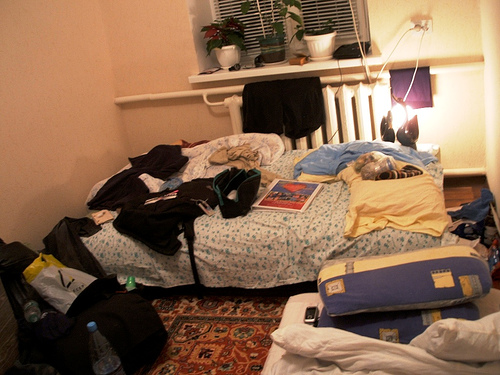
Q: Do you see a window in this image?
A: Yes, there is a window.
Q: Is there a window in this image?
A: Yes, there is a window.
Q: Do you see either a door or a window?
A: Yes, there is a window.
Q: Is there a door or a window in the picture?
A: Yes, there is a window.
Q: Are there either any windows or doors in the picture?
A: Yes, there is a window.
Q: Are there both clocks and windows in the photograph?
A: No, there is a window but no clocks.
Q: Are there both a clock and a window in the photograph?
A: No, there is a window but no clocks.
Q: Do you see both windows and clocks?
A: No, there is a window but no clocks.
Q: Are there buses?
A: No, there are no buses.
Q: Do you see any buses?
A: No, there are no buses.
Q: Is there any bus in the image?
A: No, there are no buses.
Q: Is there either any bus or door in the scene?
A: No, there are no buses or doors.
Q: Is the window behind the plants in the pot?
A: Yes, the window is behind the plants.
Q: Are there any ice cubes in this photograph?
A: No, there are no ice cubes.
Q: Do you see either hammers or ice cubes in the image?
A: No, there are no ice cubes or hammers.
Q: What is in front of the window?
A: The plants are in front of the window.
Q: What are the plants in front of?
A: The plants are in front of the window.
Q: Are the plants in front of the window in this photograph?
A: Yes, the plants are in front of the window.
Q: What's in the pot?
A: The plants are in the pot.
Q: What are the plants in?
A: The plants are in the pot.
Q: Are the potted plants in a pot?
A: Yes, the plants are in a pot.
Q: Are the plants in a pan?
A: No, the plants are in a pot.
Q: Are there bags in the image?
A: Yes, there is a bag.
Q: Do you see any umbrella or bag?
A: Yes, there is a bag.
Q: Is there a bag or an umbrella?
A: Yes, there is a bag.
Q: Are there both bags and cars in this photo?
A: No, there is a bag but no cars.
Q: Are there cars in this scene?
A: No, there are no cars.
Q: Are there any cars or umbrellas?
A: No, there are no cars or umbrellas.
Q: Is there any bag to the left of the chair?
A: Yes, there is a bag to the left of the chair.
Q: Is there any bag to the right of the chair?
A: No, the bag is to the left of the chair.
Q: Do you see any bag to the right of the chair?
A: No, the bag is to the left of the chair.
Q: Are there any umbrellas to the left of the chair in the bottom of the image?
A: No, there is a bag to the left of the chair.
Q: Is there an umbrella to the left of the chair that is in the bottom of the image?
A: No, there is a bag to the left of the chair.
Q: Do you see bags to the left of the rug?
A: Yes, there is a bag to the left of the rug.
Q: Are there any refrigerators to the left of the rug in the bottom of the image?
A: No, there is a bag to the left of the rug.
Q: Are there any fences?
A: No, there are no fences.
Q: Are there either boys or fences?
A: No, there are no fences or boys.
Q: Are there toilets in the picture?
A: No, there are no toilets.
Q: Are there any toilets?
A: No, there are no toilets.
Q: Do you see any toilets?
A: No, there are no toilets.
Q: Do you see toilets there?
A: No, there are no toilets.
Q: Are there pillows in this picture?
A: Yes, there is a pillow.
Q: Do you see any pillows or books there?
A: Yes, there is a pillow.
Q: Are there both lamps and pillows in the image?
A: Yes, there are both a pillow and a lamp.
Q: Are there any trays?
A: No, there are no trays.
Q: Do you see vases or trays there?
A: No, there are no trays or vases.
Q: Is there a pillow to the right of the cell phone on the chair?
A: Yes, there is a pillow to the right of the cellphone.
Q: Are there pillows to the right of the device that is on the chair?
A: Yes, there is a pillow to the right of the cellphone.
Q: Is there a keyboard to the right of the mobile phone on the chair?
A: No, there is a pillow to the right of the mobile phone.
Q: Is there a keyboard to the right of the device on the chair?
A: No, there is a pillow to the right of the mobile phone.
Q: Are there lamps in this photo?
A: Yes, there is a lamp.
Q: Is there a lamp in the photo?
A: Yes, there is a lamp.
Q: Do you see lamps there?
A: Yes, there is a lamp.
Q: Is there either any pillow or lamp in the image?
A: Yes, there is a lamp.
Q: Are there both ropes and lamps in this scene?
A: No, there is a lamp but no ropes.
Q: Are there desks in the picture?
A: No, there are no desks.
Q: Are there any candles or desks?
A: No, there are no desks or candles.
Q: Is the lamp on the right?
A: Yes, the lamp is on the right of the image.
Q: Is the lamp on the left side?
A: No, the lamp is on the right of the image.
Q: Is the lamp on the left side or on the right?
A: The lamp is on the right of the image.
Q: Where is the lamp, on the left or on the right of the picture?
A: The lamp is on the right of the image.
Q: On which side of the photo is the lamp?
A: The lamp is on the right of the image.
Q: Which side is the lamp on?
A: The lamp is on the right of the image.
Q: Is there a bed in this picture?
A: Yes, there is a bed.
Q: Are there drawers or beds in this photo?
A: Yes, there is a bed.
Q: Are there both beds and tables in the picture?
A: No, there is a bed but no tables.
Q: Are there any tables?
A: No, there are no tables.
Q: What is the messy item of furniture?
A: The piece of furniture is a bed.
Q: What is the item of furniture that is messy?
A: The piece of furniture is a bed.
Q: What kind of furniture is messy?
A: The furniture is a bed.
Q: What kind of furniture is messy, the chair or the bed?
A: The bed is messy.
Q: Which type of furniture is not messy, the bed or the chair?
A: The chair is not messy.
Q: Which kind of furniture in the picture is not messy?
A: The furniture is a chair.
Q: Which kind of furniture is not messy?
A: The furniture is a chair.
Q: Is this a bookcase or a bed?
A: This is a bed.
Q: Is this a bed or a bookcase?
A: This is a bed.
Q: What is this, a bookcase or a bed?
A: This is a bed.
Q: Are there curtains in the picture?
A: No, there are no curtains.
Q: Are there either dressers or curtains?
A: No, there are no curtains or dressers.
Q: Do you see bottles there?
A: Yes, there is a bottle.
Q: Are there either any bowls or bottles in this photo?
A: Yes, there is a bottle.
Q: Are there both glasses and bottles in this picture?
A: No, there is a bottle but no glasses.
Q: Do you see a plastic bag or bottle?
A: Yes, there is a plastic bottle.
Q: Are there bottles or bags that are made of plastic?
A: Yes, the bottle is made of plastic.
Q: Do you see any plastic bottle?
A: Yes, there is a bottle that is made of plastic.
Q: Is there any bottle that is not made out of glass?
A: Yes, there is a bottle that is made of plastic.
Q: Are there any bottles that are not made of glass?
A: Yes, there is a bottle that is made of plastic.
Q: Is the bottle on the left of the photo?
A: Yes, the bottle is on the left of the image.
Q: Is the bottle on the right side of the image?
A: No, the bottle is on the left of the image.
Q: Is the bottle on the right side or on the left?
A: The bottle is on the left of the image.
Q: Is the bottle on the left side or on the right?
A: The bottle is on the left of the image.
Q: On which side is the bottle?
A: The bottle is on the left of the image.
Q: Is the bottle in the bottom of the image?
A: Yes, the bottle is in the bottom of the image.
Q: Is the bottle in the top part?
A: No, the bottle is in the bottom of the image.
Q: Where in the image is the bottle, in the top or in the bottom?
A: The bottle is in the bottom of the image.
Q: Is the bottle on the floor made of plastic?
A: Yes, the bottle is made of plastic.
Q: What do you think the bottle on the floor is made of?
A: The bottle is made of plastic.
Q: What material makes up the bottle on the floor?
A: The bottle is made of plastic.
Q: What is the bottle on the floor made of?
A: The bottle is made of plastic.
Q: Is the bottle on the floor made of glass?
A: No, the bottle is made of plastic.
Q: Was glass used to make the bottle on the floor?
A: No, the bottle is made of plastic.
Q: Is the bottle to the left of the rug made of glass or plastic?
A: The bottle is made of plastic.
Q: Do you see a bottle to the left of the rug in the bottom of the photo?
A: Yes, there is a bottle to the left of the rug.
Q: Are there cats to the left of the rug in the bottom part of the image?
A: No, there is a bottle to the left of the rug.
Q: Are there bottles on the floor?
A: Yes, there is a bottle on the floor.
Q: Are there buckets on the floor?
A: No, there is a bottle on the floor.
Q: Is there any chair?
A: Yes, there is a chair.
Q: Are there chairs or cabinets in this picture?
A: Yes, there is a chair.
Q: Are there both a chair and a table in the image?
A: No, there is a chair but no tables.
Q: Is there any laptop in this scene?
A: No, there are no laptops.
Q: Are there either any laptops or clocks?
A: No, there are no laptops or clocks.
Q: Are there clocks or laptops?
A: No, there are no laptops or clocks.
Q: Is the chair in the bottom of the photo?
A: Yes, the chair is in the bottom of the image.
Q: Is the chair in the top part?
A: No, the chair is in the bottom of the image.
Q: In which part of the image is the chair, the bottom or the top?
A: The chair is in the bottom of the image.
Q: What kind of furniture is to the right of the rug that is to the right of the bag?
A: The piece of furniture is a chair.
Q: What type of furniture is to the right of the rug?
A: The piece of furniture is a chair.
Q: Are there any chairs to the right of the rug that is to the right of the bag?
A: Yes, there is a chair to the right of the rug.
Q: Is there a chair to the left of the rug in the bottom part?
A: No, the chair is to the right of the rug.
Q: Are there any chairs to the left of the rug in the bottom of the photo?
A: No, the chair is to the right of the rug.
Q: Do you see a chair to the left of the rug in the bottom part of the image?
A: No, the chair is to the right of the rug.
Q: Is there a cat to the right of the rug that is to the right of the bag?
A: No, there is a chair to the right of the rug.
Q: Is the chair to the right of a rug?
A: Yes, the chair is to the right of a rug.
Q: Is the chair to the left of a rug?
A: No, the chair is to the right of a rug.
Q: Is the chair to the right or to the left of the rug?
A: The chair is to the right of the rug.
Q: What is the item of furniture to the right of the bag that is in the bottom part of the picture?
A: The piece of furniture is a chair.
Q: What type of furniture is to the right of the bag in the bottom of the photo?
A: The piece of furniture is a chair.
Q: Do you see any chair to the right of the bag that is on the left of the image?
A: Yes, there is a chair to the right of the bag.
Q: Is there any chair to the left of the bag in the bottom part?
A: No, the chair is to the right of the bag.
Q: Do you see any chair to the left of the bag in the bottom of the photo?
A: No, the chair is to the right of the bag.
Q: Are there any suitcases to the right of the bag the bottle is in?
A: No, there is a chair to the right of the bag.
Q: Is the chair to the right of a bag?
A: Yes, the chair is to the right of a bag.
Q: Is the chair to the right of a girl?
A: No, the chair is to the right of a bag.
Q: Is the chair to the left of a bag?
A: No, the chair is to the right of a bag.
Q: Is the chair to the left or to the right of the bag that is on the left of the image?
A: The chair is to the right of the bag.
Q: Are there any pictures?
A: No, there are no pictures.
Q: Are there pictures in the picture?
A: No, there are no pictures.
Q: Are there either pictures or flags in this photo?
A: No, there are no pictures or flags.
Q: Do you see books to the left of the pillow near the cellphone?
A: Yes, there is a book to the left of the pillow.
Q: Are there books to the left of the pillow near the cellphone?
A: Yes, there is a book to the left of the pillow.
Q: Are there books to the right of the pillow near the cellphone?
A: No, the book is to the left of the pillow.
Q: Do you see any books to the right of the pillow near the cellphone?
A: No, the book is to the left of the pillow.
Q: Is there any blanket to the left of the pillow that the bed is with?
A: No, there is a book to the left of the pillow.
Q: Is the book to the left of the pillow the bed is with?
A: Yes, the book is to the left of the pillow.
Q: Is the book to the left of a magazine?
A: No, the book is to the left of the pillow.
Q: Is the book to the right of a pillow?
A: No, the book is to the left of a pillow.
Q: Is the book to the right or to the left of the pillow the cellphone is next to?
A: The book is to the left of the pillow.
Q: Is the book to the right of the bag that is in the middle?
A: Yes, the book is to the right of the bag.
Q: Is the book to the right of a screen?
A: No, the book is to the right of the bag.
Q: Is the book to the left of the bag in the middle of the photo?
A: No, the book is to the right of the bag.